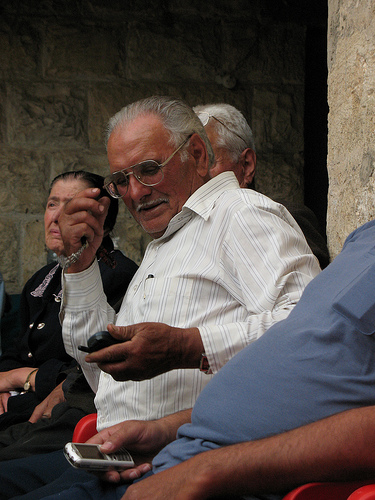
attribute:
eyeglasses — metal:
[109, 130, 193, 200]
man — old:
[0, 95, 324, 499]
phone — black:
[77, 329, 120, 356]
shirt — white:
[59, 169, 323, 432]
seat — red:
[70, 410, 102, 446]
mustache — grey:
[136, 199, 166, 212]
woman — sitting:
[0, 169, 139, 429]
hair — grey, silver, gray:
[103, 95, 217, 172]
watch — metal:
[52, 238, 90, 270]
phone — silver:
[64, 440, 137, 472]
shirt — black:
[0, 245, 139, 422]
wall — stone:
[0, 0, 308, 296]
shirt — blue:
[153, 222, 374, 479]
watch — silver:
[197, 351, 214, 376]